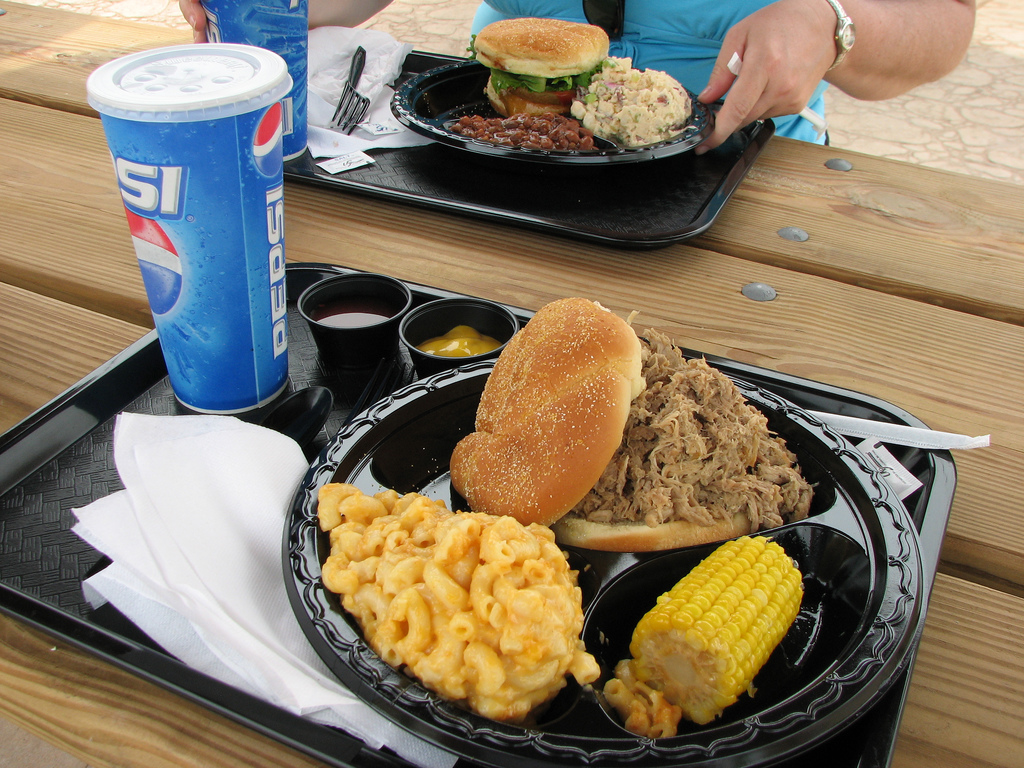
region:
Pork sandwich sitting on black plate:
[448, 295, 818, 553]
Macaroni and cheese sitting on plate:
[316, 480, 598, 725]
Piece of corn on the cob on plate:
[626, 534, 808, 725]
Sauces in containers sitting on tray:
[294, 272, 519, 368]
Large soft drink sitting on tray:
[85, 38, 297, 416]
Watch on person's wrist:
[824, 0, 856, 80]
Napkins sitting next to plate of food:
[68, 410, 471, 766]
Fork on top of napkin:
[300, 23, 421, 156]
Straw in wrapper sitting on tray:
[764, 402, 992, 453]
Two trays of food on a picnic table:
[0, 1, 1021, 766]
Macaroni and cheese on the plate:
[312, 462, 595, 731]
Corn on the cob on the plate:
[626, 524, 807, 722]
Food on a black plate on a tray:
[280, 295, 928, 763]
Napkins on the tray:
[71, 405, 451, 766]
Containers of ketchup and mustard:
[297, 252, 520, 380]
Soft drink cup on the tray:
[79, 24, 294, 416]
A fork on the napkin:
[325, 36, 370, 139]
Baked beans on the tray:
[445, 93, 595, 157]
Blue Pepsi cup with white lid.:
[90, 39, 303, 404]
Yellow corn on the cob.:
[638, 538, 816, 710]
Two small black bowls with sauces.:
[295, 263, 515, 369]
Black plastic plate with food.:
[383, 20, 731, 170]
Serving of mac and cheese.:
[319, 479, 594, 699]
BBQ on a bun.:
[464, 304, 812, 545]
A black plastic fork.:
[327, 38, 378, 141]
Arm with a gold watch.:
[695, 1, 978, 153]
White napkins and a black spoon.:
[84, 376, 451, 766]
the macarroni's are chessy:
[405, 543, 495, 629]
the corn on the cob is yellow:
[711, 575, 760, 627]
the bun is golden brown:
[511, 366, 576, 421]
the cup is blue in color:
[204, 288, 268, 361]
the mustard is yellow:
[442, 326, 481, 352]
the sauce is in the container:
[322, 274, 389, 336]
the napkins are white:
[180, 499, 245, 570]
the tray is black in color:
[502, 170, 583, 222]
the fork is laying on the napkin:
[318, 41, 388, 137]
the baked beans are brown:
[503, 110, 560, 150]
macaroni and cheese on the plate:
[307, 476, 595, 712]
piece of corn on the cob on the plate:
[651, 527, 801, 715]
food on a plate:
[330, 495, 410, 698]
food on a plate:
[627, 544, 827, 697]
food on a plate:
[495, 593, 584, 723]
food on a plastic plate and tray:
[3, 265, 958, 766]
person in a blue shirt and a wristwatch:
[695, 3, 1006, 242]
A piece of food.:
[410, 545, 484, 615]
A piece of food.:
[678, 450, 697, 470]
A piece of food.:
[613, 677, 649, 707]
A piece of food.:
[556, 630, 591, 685]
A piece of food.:
[392, 498, 425, 537]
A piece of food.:
[429, 512, 458, 567]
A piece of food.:
[476, 529, 508, 569]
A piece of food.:
[702, 580, 726, 603]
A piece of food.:
[718, 558, 732, 578]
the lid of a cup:
[90, 16, 280, 147]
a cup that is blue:
[58, 101, 315, 396]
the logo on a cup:
[111, 183, 201, 314]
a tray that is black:
[49, 256, 961, 765]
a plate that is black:
[313, 356, 933, 765]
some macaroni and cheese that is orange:
[307, 470, 582, 736]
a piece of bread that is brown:
[465, 312, 628, 548]